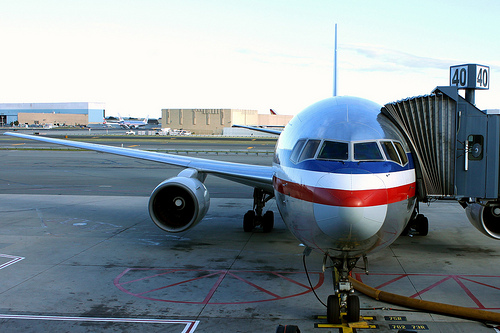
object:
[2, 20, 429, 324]
plane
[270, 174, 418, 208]
stripe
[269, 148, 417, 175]
stripe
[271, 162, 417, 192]
stripe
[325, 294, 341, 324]
wheels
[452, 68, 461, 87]
numbers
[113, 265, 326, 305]
symbol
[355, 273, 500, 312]
symbol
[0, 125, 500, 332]
ground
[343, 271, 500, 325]
pipe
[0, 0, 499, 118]
sky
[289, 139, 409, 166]
inside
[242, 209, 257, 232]
wheels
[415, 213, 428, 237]
wheels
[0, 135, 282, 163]
runway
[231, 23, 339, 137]
tail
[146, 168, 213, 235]
engine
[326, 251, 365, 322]
landing gear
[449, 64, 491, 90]
sign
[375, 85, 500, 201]
skybridge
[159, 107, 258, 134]
building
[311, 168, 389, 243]
nose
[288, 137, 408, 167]
cockpit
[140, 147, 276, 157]
railing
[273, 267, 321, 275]
lines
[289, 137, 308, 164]
windows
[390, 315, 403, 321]
yellow lettering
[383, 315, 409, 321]
black background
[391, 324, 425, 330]
yellow lettering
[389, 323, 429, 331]
black background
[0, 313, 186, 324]
lines